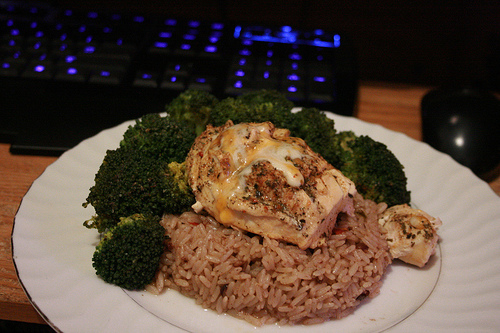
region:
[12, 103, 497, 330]
the plate has a gold trim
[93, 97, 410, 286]
the broccoli is dark green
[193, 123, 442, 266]
the chicken breast is on rice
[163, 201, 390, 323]
the rice is brown rice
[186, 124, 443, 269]
the chicken has herbs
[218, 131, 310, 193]
the chicken has cheese oozing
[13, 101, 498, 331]
the plate has food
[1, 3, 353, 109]
the keyboard has a blue light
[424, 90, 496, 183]
the mouse is black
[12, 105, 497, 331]
the plate is white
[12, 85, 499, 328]
Food on a plate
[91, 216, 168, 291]
Broccoli on the plate of food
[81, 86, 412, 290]
Array of broccoli on the plate of food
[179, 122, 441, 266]
Baked chicken leg on the plate of food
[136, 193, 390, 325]
Rice on the plate of food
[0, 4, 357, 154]
Computer keyboard on the table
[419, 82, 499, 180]
Computer mouse on the table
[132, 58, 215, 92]
Arrow keys of the keyboard on the table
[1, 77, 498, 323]
Table used to hold the keyboard and plate of food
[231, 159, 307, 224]
Piece of skin of the baked chicken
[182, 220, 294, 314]
the rice is brown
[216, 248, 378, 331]
the rice is brown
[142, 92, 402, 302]
a meat on top of the rice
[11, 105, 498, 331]
a white dinner plate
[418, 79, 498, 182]
a black computer mouse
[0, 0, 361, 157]
a black computer keyboard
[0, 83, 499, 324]
a wooden desk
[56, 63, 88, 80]
an illuminated key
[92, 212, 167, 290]
a sprig of broccoli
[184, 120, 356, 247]
a stuffed chicken breast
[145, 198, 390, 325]
a pile of rice pilaf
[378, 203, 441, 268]
a small piece of chicken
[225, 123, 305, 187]
melted cheese on the chicken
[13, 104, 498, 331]
A white plate filled with food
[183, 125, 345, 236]
A portion of baked chicken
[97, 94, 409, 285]
Cooked green broccoli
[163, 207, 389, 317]
A large serving of rice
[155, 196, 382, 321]
A large serving of brown rice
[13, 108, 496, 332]
A large plate with a chicken dinner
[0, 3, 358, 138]
A computer keyboard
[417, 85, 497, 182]
A computer mouse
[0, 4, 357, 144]
A computer keyboard with illuminated keys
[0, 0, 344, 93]
Brigtly illuminated keyboard keys